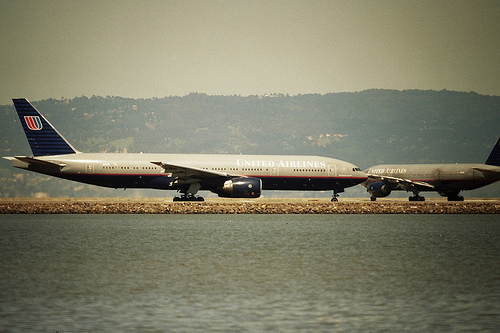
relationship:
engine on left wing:
[370, 184, 390, 194] [362, 165, 422, 198]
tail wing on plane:
[8, 91, 98, 197] [0, 97, 368, 202]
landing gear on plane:
[170, 194, 337, 204] [0, 97, 368, 202]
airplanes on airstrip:
[3, 88, 369, 208] [39, 196, 484, 208]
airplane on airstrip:
[360, 136, 500, 202] [39, 196, 484, 208]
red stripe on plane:
[242, 161, 363, 186] [32, 91, 469, 216]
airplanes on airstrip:
[3, 88, 369, 208] [0, 196, 500, 208]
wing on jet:
[148, 160, 248, 191] [0, 96, 375, 202]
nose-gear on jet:
[328, 185, 345, 202] [20, 121, 363, 202]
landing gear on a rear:
[172, 182, 204, 202] [68, 141, 163, 198]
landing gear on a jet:
[172, 182, 204, 202] [3, 95, 373, 214]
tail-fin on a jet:
[0, 96, 78, 160] [3, 95, 373, 214]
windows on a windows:
[243, 166, 269, 171] [292, 168, 332, 171]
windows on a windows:
[225, 166, 237, 171] [292, 168, 332, 171]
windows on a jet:
[292, 168, 332, 171] [0, 96, 375, 202]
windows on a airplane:
[292, 168, 332, 171] [360, 136, 500, 202]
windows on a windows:
[140, 165, 157, 170] [292, 168, 332, 171]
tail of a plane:
[2, 95, 75, 175] [0, 97, 368, 202]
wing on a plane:
[132, 163, 237, 198] [8, 83, 415, 224]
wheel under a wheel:
[173, 195, 180, 201] [178, 195, 187, 201]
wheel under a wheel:
[173, 195, 180, 201] [187, 194, 197, 201]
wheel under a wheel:
[173, 195, 180, 201] [194, 195, 204, 201]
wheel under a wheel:
[173, 195, 180, 201] [330, 197, 337, 202]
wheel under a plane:
[173, 195, 180, 201] [0, 97, 368, 202]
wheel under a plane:
[173, 195, 180, 201] [363, 136, 499, 200]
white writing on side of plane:
[228, 156, 333, 170] [8, 83, 415, 224]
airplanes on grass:
[3, 88, 493, 208] [11, 193, 221, 203]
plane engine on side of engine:
[213, 175, 264, 196] [368, 182, 392, 198]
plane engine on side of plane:
[213, 175, 264, 196] [0, 97, 368, 202]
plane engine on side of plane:
[213, 175, 264, 196] [363, 136, 499, 200]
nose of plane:
[338, 158, 368, 190] [0, 97, 368, 202]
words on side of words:
[231, 158, 332, 170] [363, 166, 408, 176]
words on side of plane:
[231, 158, 332, 170] [0, 97, 368, 202]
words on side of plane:
[231, 158, 332, 170] [359, 142, 499, 201]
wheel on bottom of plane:
[323, 185, 343, 204] [0, 97, 368, 202]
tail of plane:
[2, 95, 75, 175] [0, 97, 368, 202]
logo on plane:
[24, 115, 44, 130] [0, 97, 368, 202]